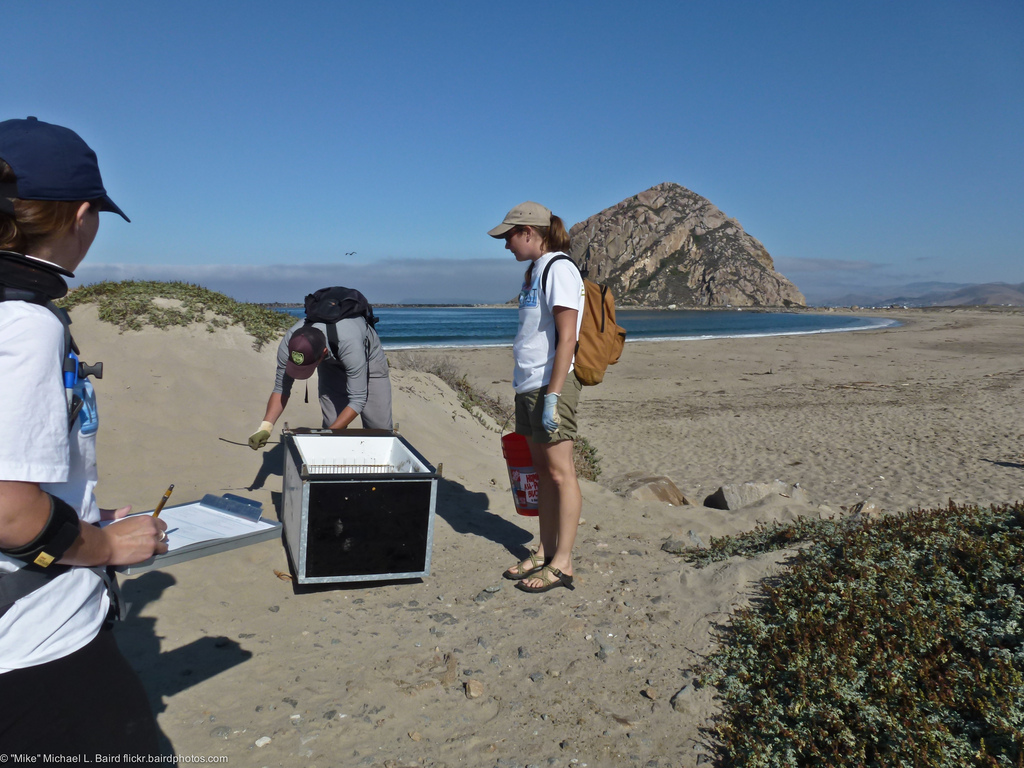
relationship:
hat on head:
[0, 113, 145, 230] [1, 111, 114, 269]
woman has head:
[3, 111, 174, 757] [1, 111, 114, 269]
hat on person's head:
[267, 315, 347, 396] [269, 321, 378, 447]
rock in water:
[538, 162, 794, 323] [559, 284, 862, 351]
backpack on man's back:
[287, 270, 387, 331] [270, 279, 398, 362]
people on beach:
[0, 78, 655, 554] [8, 63, 1018, 736]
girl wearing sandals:
[471, 184, 610, 403] [494, 536, 588, 608]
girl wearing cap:
[453, 169, 644, 342] [488, 190, 588, 284]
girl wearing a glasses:
[469, 195, 604, 420] [497, 214, 530, 247]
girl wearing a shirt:
[466, 169, 631, 347] [505, 247, 586, 390]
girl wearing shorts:
[481, 180, 577, 289] [503, 357, 583, 451]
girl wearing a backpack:
[481, 175, 600, 336] [570, 258, 637, 403]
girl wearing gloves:
[469, 184, 638, 418] [525, 368, 565, 446]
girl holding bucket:
[453, 191, 605, 362] [497, 409, 571, 526]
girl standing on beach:
[466, 167, 637, 317] [153, 342, 961, 764]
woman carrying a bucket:
[460, 173, 603, 325] [576, 262, 628, 390]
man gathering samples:
[250, 273, 374, 401] [214, 407, 286, 459]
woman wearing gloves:
[471, 180, 593, 334] [536, 392, 576, 434]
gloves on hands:
[536, 392, 576, 434] [514, 368, 599, 464]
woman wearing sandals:
[455, 167, 622, 330] [505, 530, 588, 593]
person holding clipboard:
[2, 102, 165, 347] [104, 458, 316, 625]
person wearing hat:
[2, 106, 160, 424] [4, 108, 205, 320]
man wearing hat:
[244, 284, 391, 408] [278, 312, 326, 390]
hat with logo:
[278, 312, 326, 390] [281, 342, 305, 369]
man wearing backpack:
[255, 312, 381, 429] [298, 275, 392, 345]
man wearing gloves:
[250, 290, 402, 414] [239, 420, 276, 462]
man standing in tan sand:
[250, 281, 406, 448] [127, 340, 251, 446]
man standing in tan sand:
[1, 109, 183, 758] [310, 612, 481, 742]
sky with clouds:
[189, 50, 667, 146] [262, 262, 505, 289]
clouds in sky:
[262, 262, 505, 289] [189, 50, 667, 146]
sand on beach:
[632, 325, 797, 548] [647, 271, 810, 369]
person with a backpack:
[245, 281, 390, 426] [293, 260, 356, 334]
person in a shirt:
[9, 111, 139, 762] [1, 309, 110, 601]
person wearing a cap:
[489, 212, 593, 588] [487, 189, 559, 246]